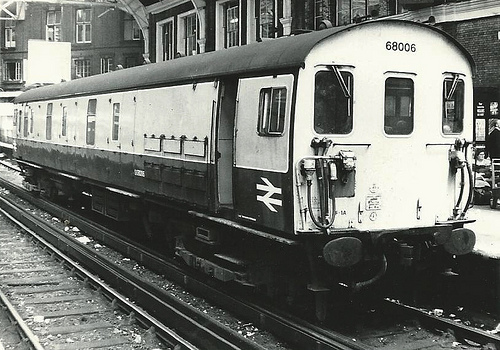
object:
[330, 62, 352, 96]
wipers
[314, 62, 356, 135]
window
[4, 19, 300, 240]
train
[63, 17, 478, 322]
train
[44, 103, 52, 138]
window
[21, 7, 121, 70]
brick building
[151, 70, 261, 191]
door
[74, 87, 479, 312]
train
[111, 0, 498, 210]
building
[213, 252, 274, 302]
wheels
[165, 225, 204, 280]
wheels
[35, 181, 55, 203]
wheels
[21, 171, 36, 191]
wheels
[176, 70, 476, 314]
train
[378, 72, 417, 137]
window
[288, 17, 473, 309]
train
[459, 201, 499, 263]
platform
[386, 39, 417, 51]
number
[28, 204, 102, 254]
litter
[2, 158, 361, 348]
rail way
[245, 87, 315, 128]
window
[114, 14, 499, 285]
train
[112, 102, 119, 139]
window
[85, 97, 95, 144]
window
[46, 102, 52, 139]
window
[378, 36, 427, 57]
number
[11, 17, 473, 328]
train car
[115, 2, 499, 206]
station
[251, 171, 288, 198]
pattern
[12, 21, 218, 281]
car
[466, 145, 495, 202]
woman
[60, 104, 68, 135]
window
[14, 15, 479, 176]
train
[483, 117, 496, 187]
person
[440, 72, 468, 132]
window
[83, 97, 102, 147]
train window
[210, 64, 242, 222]
door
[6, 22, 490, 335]
train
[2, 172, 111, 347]
tracks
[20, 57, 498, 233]
car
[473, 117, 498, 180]
people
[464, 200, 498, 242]
walkway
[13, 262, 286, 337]
gravel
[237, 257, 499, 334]
rocks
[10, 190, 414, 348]
tracks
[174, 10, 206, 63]
window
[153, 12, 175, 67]
window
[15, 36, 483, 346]
train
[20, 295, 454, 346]
train tracks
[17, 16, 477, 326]
car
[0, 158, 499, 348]
railway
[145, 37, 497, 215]
train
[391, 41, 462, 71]
number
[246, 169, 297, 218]
arrows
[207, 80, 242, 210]
door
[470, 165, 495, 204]
chair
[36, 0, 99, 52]
windows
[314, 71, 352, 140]
window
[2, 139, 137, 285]
strip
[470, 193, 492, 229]
platform